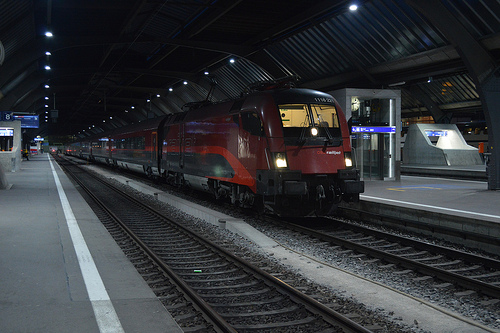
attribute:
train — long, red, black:
[48, 75, 361, 223]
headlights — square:
[266, 144, 357, 170]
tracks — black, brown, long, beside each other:
[61, 178, 384, 327]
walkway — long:
[8, 145, 94, 312]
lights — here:
[35, 28, 57, 124]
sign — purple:
[350, 123, 402, 138]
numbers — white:
[312, 94, 339, 108]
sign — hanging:
[7, 112, 52, 133]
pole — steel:
[385, 133, 400, 180]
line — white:
[41, 187, 128, 312]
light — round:
[309, 124, 319, 142]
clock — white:
[344, 95, 364, 117]